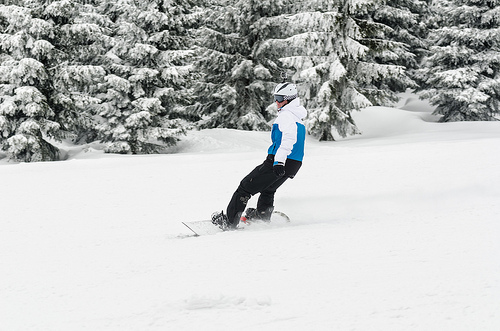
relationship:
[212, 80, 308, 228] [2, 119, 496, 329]
man snowboarding on snow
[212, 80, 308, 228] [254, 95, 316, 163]
man wearing blue jacket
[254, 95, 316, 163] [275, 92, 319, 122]
blue jacket has a hood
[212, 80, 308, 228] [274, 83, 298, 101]
man wearing helmet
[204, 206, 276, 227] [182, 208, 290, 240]
feet on snowboard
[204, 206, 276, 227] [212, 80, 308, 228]
feet of man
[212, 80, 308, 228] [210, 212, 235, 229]
man wearing shoe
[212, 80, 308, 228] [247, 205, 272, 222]
man wearing shoe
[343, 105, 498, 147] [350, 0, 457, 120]
snow around pine trees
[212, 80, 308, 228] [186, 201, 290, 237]
man riding skate board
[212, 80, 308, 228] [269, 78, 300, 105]
man wearing a hat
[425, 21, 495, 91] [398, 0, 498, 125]
snow covering tree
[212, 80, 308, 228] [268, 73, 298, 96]
man wearing white hat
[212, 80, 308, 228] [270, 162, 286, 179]
man wearing black mitten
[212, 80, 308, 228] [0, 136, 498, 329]
man snowboarding on slope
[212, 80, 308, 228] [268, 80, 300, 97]
man wearing helmet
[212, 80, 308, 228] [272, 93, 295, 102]
man wearing goggles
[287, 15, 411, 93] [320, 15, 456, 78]
snow covering trees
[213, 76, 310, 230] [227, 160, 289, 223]
skateboarder wearing black pants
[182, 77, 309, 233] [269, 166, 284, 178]
skier wearing gloves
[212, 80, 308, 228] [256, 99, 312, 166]
man wearing jacket